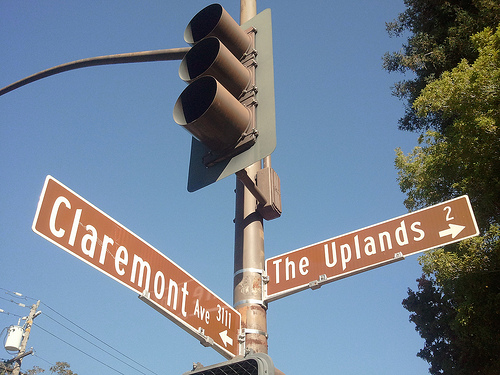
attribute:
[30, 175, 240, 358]
sign — brown, hanging, white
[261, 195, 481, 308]
sign — brown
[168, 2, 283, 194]
stop light — mounted, brown, metal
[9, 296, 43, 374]
pole — electrical, light grey, wooden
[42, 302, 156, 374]
wire — electrical, overhead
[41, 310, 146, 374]
wire — electrical, overhead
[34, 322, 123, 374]
wire — electrical, overhead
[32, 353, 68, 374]
wire — electrical, overhead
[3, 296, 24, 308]
wire — electrical, overhead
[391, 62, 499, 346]
tree — tall, green, leafy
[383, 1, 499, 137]
tree — tall, green, leafy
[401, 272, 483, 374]
tree — tall, green, leafy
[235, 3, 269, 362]
pole — brown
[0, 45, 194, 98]
street lamp — grey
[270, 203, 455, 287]
lettering — white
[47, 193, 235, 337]
lettering — white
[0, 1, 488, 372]
sky — clear, medium blue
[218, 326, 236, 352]
arrow — white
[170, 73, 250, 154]
cover — brown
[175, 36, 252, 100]
cover — brown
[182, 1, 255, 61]
cover — brown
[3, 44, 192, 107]
pole — metal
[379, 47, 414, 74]
leaves — green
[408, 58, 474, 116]
leaves — green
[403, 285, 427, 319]
leaves — green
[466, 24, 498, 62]
leaves — green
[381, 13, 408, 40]
leaves — green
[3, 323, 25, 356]
box — cylindrical, metal, white